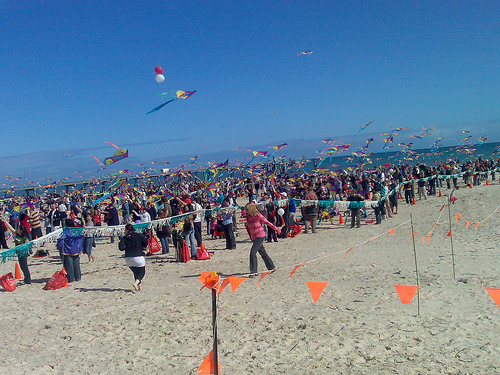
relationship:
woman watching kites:
[118, 224, 147, 292] [0, 122, 495, 174]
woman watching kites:
[246, 201, 283, 273] [0, 122, 495, 174]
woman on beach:
[118, 224, 147, 292] [3, 178, 494, 373]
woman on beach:
[246, 201, 283, 273] [3, 178, 494, 373]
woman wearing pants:
[118, 224, 147, 292] [129, 266, 145, 282]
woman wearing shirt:
[246, 201, 283, 273] [246, 211, 278, 238]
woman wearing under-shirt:
[118, 224, 147, 292] [124, 255, 146, 266]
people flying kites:
[0, 156, 499, 249] [0, 122, 495, 174]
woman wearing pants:
[246, 201, 283, 273] [249, 239, 275, 274]